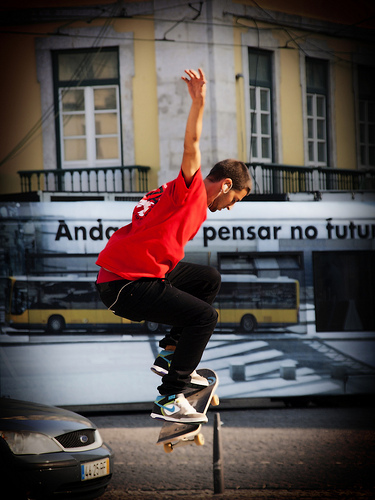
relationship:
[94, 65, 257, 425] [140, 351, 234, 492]
boy doing skateboard trick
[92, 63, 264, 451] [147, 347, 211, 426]
man wearing shoes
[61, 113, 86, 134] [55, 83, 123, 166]
glass pane in window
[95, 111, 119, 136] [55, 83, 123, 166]
small pane in window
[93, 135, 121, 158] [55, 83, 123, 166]
small pane in window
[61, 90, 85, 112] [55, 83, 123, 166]
glass pane in window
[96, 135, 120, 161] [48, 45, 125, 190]
glass in window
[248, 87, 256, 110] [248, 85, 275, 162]
glass in window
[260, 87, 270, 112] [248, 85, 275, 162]
glass in window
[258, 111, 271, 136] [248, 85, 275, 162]
glass in window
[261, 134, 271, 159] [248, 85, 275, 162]
glass in window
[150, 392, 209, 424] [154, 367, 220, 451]
shoe on skateboard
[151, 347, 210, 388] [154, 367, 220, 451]
shoe on skateboard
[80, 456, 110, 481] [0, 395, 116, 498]
license plate on car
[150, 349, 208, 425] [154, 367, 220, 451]
shoes on skateboard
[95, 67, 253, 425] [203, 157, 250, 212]
man has head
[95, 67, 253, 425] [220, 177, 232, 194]
man has ear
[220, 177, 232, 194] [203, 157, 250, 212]
ear on head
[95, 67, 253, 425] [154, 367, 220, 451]
man on skateboard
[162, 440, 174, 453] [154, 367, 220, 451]
wheel on skateboard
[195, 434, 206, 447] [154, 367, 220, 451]
wheel on skateboard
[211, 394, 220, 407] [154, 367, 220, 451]
wheel on skateboard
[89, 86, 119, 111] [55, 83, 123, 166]
glass in window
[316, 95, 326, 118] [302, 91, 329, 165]
glass in window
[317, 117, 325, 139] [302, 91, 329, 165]
glass in window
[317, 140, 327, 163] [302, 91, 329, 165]
glass in window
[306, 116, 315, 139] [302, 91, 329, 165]
glass in window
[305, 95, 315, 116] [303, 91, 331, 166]
glass in window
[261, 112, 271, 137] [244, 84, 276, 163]
glass in window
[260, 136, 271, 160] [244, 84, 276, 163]
glass in window